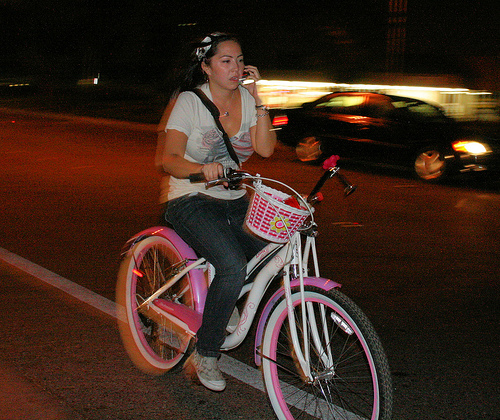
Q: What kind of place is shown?
A: It is a street.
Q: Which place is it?
A: It is a street.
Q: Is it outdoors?
A: Yes, it is outdoors.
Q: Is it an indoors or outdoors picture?
A: It is outdoors.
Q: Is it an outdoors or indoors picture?
A: It is outdoors.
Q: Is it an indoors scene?
A: No, it is outdoors.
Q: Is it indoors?
A: No, it is outdoors.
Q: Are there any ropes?
A: No, there are no ropes.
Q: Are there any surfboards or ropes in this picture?
A: No, there are no ropes or surfboards.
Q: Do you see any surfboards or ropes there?
A: No, there are no ropes or surfboards.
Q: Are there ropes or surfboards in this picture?
A: No, there are no ropes or surfboards.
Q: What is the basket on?
A: The basket is on the bike.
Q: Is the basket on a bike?
A: Yes, the basket is on a bike.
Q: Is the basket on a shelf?
A: No, the basket is on a bike.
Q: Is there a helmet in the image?
A: No, there are no helmets.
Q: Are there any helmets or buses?
A: No, there are no helmets or buses.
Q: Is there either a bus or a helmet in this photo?
A: No, there are no helmets or buses.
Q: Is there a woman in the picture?
A: Yes, there is a woman.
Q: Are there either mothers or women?
A: Yes, there is a woman.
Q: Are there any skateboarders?
A: No, there are no skateboarders.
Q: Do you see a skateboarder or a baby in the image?
A: No, there are no skateboarders or babies.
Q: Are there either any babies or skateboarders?
A: No, there are no skateboarders or babies.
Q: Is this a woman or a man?
A: This is a woman.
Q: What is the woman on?
A: The woman is on the bike.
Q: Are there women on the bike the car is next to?
A: Yes, there is a woman on the bike.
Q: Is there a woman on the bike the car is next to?
A: Yes, there is a woman on the bike.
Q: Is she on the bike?
A: Yes, the woman is on the bike.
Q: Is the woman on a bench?
A: No, the woman is on the bike.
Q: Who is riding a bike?
A: The woman is riding a bike.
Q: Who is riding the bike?
A: The woman is riding a bike.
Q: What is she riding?
A: The woman is riding a bike.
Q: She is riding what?
A: The woman is riding a bike.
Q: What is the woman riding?
A: The woman is riding a bike.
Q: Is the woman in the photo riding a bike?
A: Yes, the woman is riding a bike.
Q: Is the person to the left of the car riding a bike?
A: Yes, the woman is riding a bike.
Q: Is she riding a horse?
A: No, the woman is riding a bike.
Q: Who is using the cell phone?
A: The woman is using the cell phone.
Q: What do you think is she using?
A: The woman is using a cellphone.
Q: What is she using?
A: The woman is using a cellphone.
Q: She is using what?
A: The woman is using a cellphone.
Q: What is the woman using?
A: The woman is using a cellphone.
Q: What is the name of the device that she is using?
A: The device is a cell phone.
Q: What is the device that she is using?
A: The device is a cell phone.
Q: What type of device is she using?
A: The woman is using a cellphone.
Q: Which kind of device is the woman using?
A: The woman is using a cellphone.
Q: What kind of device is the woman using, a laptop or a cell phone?
A: The woman is using a cell phone.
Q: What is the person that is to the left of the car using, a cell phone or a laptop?
A: The woman is using a cell phone.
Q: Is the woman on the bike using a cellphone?
A: Yes, the woman is using a cellphone.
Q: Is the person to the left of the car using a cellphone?
A: Yes, the woman is using a cellphone.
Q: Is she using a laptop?
A: No, the woman is using a cellphone.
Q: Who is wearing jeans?
A: The woman is wearing jeans.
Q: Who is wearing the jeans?
A: The woman is wearing jeans.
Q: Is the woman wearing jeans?
A: Yes, the woman is wearing jeans.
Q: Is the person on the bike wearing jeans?
A: Yes, the woman is wearing jeans.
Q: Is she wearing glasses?
A: No, the woman is wearing jeans.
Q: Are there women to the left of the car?
A: Yes, there is a woman to the left of the car.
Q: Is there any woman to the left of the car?
A: Yes, there is a woman to the left of the car.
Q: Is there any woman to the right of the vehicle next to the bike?
A: No, the woman is to the left of the car.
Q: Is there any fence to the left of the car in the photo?
A: No, there is a woman to the left of the car.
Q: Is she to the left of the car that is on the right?
A: Yes, the woman is to the left of the car.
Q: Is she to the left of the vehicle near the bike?
A: Yes, the woman is to the left of the car.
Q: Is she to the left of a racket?
A: No, the woman is to the left of the car.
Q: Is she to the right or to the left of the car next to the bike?
A: The woman is to the left of the car.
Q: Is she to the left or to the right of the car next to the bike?
A: The woman is to the left of the car.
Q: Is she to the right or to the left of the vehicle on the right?
A: The woman is to the left of the car.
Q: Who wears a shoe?
A: The woman wears a shoe.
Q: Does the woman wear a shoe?
A: Yes, the woman wears a shoe.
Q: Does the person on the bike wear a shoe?
A: Yes, the woman wears a shoe.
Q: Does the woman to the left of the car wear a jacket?
A: No, the woman wears a shoe.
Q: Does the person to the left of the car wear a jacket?
A: No, the woman wears a shoe.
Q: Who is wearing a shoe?
A: The woman is wearing a shoe.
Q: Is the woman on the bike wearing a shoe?
A: Yes, the woman is wearing a shoe.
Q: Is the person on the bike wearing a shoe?
A: Yes, the woman is wearing a shoe.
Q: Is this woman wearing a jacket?
A: No, the woman is wearing a shoe.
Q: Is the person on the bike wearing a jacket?
A: No, the woman is wearing a shoe.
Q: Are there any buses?
A: No, there are no buses.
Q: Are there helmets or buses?
A: No, there are no buses or helmets.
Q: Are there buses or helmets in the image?
A: No, there are no buses or helmets.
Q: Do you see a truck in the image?
A: No, there are no trucks.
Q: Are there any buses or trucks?
A: No, there are no trucks or buses.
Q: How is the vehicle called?
A: The vehicle is a car.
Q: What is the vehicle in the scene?
A: The vehicle is a car.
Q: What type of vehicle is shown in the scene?
A: The vehicle is a car.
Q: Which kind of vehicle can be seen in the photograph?
A: The vehicle is a car.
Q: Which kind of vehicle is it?
A: The vehicle is a car.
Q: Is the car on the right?
A: Yes, the car is on the right of the image.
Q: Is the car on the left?
A: No, the car is on the right of the image.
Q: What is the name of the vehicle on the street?
A: The vehicle is a car.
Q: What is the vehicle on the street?
A: The vehicle is a car.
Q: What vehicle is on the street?
A: The vehicle is a car.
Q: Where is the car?
A: The car is on the street.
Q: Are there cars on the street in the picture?
A: Yes, there is a car on the street.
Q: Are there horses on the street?
A: No, there is a car on the street.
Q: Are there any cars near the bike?
A: Yes, there is a car near the bike.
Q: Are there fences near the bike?
A: No, there is a car near the bike.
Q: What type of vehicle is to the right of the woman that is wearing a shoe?
A: The vehicle is a car.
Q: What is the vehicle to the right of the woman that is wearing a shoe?
A: The vehicle is a car.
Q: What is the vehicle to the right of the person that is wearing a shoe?
A: The vehicle is a car.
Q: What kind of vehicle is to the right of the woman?
A: The vehicle is a car.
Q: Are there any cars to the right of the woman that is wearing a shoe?
A: Yes, there is a car to the right of the woman.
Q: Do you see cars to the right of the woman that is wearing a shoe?
A: Yes, there is a car to the right of the woman.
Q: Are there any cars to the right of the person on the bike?
A: Yes, there is a car to the right of the woman.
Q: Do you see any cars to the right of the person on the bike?
A: Yes, there is a car to the right of the woman.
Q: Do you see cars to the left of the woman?
A: No, the car is to the right of the woman.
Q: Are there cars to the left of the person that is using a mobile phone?
A: No, the car is to the right of the woman.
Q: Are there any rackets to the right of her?
A: No, there is a car to the right of the woman.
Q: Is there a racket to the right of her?
A: No, there is a car to the right of the woman.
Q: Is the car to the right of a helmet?
A: No, the car is to the right of the woman.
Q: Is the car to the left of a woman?
A: No, the car is to the right of a woman.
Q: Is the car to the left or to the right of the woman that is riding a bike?
A: The car is to the right of the woman.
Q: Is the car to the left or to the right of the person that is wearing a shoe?
A: The car is to the right of the woman.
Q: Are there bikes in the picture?
A: Yes, there is a bike.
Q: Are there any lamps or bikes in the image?
A: Yes, there is a bike.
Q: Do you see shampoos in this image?
A: No, there are no shampoos.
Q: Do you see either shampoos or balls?
A: No, there are no shampoos or balls.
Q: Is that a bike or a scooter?
A: That is a bike.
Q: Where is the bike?
A: The bike is on the street.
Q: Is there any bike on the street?
A: Yes, there is a bike on the street.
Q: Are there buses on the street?
A: No, there is a bike on the street.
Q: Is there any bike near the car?
A: Yes, there is a bike near the car.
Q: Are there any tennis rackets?
A: No, there are no tennis rackets.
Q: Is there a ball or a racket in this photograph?
A: No, there are no rackets or balls.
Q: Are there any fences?
A: No, there are no fences.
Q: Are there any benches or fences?
A: No, there are no fences or benches.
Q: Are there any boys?
A: No, there are no boys.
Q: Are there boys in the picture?
A: No, there are no boys.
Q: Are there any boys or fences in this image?
A: No, there are no boys or fences.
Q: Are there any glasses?
A: No, there are no glasses.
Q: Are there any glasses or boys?
A: No, there are no glasses or boys.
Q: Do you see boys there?
A: No, there are no boys.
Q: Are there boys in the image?
A: No, there are no boys.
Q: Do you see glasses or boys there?
A: No, there are no boys or glasses.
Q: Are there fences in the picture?
A: No, there are no fences.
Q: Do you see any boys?
A: No, there are no boys.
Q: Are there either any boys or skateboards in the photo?
A: No, there are no boys or skateboards.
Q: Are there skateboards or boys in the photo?
A: No, there are no boys or skateboards.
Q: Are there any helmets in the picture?
A: No, there are no helmets.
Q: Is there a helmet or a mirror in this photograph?
A: No, there are no helmets or mirrors.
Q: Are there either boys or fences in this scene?
A: No, there are no boys or fences.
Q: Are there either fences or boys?
A: No, there are no boys or fences.